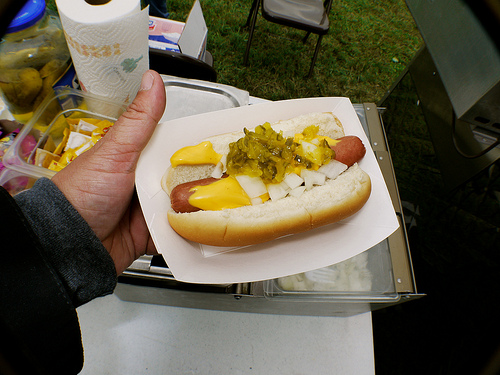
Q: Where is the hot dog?
A: In a container.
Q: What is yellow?
A: Mustard.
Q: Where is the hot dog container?
A: In a person's hand.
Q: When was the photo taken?
A: Daytime.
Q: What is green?
A: The grass.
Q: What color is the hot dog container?
A: White.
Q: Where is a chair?
A: On the grass.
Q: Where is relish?
A: On the hot dog.